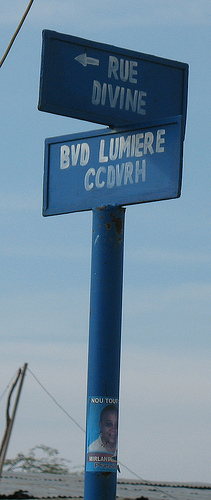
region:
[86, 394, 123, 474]
sticker on the pole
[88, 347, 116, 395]
a blue pole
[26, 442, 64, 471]
tree branches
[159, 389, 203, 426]
a cloudy blue sky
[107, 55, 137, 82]
the word rue in white paint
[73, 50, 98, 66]
an arrow pointing left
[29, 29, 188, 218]
two signs on a post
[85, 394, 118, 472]
a missing child poster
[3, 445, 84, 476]
fallen trees in the background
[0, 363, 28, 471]
a leaning power pole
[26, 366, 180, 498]
a broken power line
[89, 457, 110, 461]
white text on a flyer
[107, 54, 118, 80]
white letter on sign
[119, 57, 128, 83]
white letter on sign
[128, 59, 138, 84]
white letter on sign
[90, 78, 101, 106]
white letter on sign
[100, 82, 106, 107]
white letter on sign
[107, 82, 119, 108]
white letter on sign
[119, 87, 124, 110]
white letter on sign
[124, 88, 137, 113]
white letter on sign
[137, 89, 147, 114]
white letter on sign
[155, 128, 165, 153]
white letter on sign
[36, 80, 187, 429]
these are street signs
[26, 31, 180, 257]
this is a street corner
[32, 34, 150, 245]
the signs are blue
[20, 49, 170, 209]
the writing is white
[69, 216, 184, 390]
the pole is metal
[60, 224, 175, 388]
the pole is blue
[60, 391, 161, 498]
there is a picture on the pole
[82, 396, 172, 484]
the man is smiling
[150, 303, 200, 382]
the sky is very hazy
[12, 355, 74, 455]
this is a power line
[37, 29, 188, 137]
the top blue sign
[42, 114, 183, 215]
the bottom blue sign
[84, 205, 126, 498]
the thick blue pole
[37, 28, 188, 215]
the two blue signs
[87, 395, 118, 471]
the picture of a woman with a blue background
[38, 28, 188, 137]
the top blue sign with an arrow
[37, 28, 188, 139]
the RUE on the top blue sign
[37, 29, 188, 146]
the divine on the top blue sign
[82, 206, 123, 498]
the rusty area at the top of the blue pole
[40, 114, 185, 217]
the BVD on the blue sign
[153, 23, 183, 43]
a clear sky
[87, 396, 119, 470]
a paper on the pole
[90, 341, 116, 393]
a blue pole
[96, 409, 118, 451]
a person on the paper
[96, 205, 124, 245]
rust spots on a metal pole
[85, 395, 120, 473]
an advertisement on a metal pole